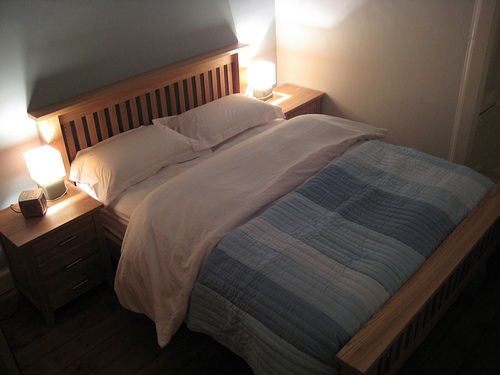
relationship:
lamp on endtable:
[33, 148, 66, 206] [0, 180, 118, 324]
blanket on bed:
[256, 209, 433, 305] [65, 111, 445, 334]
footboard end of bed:
[381, 250, 453, 350] [65, 111, 445, 334]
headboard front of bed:
[45, 48, 264, 118] [65, 111, 445, 334]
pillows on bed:
[115, 109, 254, 161] [65, 111, 445, 334]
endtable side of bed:
[0, 180, 118, 324] [65, 111, 445, 334]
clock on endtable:
[15, 189, 46, 215] [0, 180, 118, 324]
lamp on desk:
[247, 58, 291, 101] [268, 84, 326, 120]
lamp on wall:
[247, 58, 280, 101] [67, 0, 429, 75]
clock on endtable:
[15, 189, 46, 215] [10, 217, 102, 294]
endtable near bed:
[0, 180, 118, 324] [65, 111, 445, 334]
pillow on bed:
[96, 135, 187, 179] [65, 111, 445, 334]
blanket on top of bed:
[256, 209, 433, 305] [65, 111, 445, 334]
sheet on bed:
[150, 142, 254, 194] [65, 111, 445, 334]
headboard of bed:
[45, 48, 264, 118] [65, 111, 445, 334]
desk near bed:
[268, 84, 326, 120] [65, 111, 445, 334]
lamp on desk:
[247, 58, 280, 101] [275, 75, 353, 140]